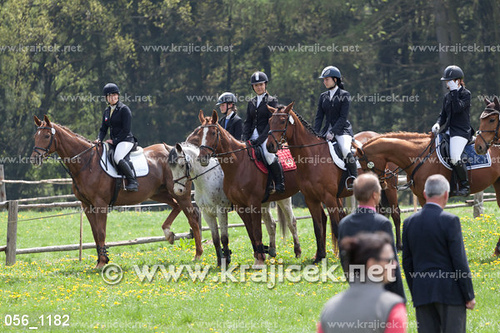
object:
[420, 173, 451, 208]
head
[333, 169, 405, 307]
man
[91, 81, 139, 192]
rider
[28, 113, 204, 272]
horse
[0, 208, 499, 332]
grass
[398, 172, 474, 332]
people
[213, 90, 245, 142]
person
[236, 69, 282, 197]
person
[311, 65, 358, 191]
person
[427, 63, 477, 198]
person